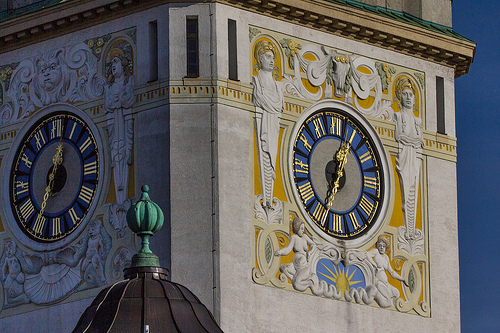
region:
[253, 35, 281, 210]
a portrait in a wall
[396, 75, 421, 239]
a portrait in a wall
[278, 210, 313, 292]
a portrait in a wall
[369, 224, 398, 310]
a portrait in a wall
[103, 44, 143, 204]
a portrait in a wall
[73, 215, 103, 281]
a portrait in a wall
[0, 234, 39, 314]
a portrait in a wall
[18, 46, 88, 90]
a portrait in a wall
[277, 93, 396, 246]
a watch in a wall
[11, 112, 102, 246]
a watch in a wall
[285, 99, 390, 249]
A blue and white clock.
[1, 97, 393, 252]
Two clocks on a tower.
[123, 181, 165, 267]
A green tower topping.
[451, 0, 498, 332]
A bright blue sky.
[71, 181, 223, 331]
Part of a tower.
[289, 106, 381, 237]
A face to a clock.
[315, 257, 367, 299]
The sun and sky.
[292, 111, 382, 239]
Numbers on a clock.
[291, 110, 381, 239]
Roman numerals on a clock.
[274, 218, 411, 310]
Two sculptered women on a building.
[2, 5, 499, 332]
Two clocks on the historical building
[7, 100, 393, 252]
Clocks on the historical building's exterior walls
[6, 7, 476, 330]
Stone exterior walls on building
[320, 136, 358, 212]
Gold hour and minute hands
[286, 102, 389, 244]
Clock with gold hour and minute hands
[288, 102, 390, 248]
Roman numerals on the clock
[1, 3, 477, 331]
Historical architectural art structure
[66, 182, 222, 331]
Top of the another structure on the historical building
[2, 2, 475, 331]
Two clocks with gold hour and minute hands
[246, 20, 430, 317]
Artifact on the historical building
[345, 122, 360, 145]
Roman number one on clock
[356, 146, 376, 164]
Roman number two on clock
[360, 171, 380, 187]
Roman number three on clock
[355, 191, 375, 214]
Roman number four on clock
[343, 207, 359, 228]
Roman number five on clock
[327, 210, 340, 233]
Roman number six on clock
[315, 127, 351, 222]
Yellow hands of clock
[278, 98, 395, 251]
Blue, yellow and gray face of clock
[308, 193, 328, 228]
Roman number seven on clock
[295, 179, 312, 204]
Roman number eight on clock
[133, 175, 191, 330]
Green decorative object on top of building.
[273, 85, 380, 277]
Clock has blue and gray face.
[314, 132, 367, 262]
Clock has gold hands.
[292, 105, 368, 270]
Clock has gold numbers.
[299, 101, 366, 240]
Numbers on clock are roman numeral.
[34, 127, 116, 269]
Gold hands on clock.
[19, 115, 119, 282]
Clock has blue and gray face.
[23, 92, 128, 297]
Numbers on clock are roman numeral.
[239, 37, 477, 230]
Statues of people cut out in side of building.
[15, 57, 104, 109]
Lion face on side of building.